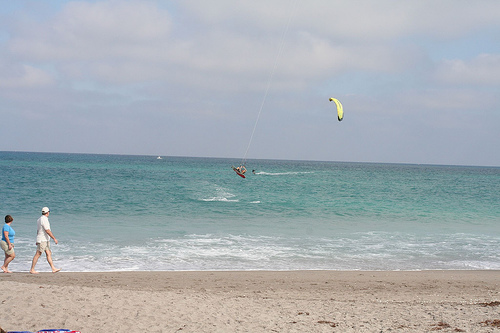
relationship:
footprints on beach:
[314, 317, 338, 326] [1, 247, 498, 329]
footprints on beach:
[481, 298, 498, 308] [1, 247, 498, 329]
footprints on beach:
[483, 317, 498, 326] [1, 247, 498, 329]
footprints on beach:
[433, 320, 453, 329] [1, 247, 498, 329]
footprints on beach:
[450, 327, 465, 331] [1, 247, 498, 329]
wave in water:
[189, 181, 261, 206] [1, 148, 497, 274]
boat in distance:
[155, 147, 170, 164] [2, 5, 498, 259]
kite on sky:
[324, 93, 348, 124] [4, 5, 494, 166]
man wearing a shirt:
[24, 204, 66, 279] [35, 214, 60, 246]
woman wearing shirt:
[0, 214, 17, 277] [0, 228, 18, 242]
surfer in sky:
[225, 156, 255, 185] [427, 36, 492, 56]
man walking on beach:
[24, 204, 66, 279] [2, 269, 484, 327]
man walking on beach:
[246, 160, 265, 178] [5, 236, 494, 290]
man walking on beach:
[24, 204, 66, 279] [51, 278, 134, 312]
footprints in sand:
[144, 279, 228, 328] [269, 260, 461, 322]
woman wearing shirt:
[0, 214, 17, 277] [3, 221, 15, 244]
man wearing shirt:
[24, 204, 66, 279] [32, 214, 56, 246]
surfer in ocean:
[225, 156, 255, 185] [44, 137, 480, 215]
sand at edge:
[4, 266, 499, 331] [8, 250, 499, 281]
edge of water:
[8, 250, 499, 281] [5, 150, 490, 245]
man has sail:
[246, 160, 265, 178] [320, 92, 348, 129]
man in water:
[246, 160, 265, 178] [241, 177, 387, 247]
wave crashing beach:
[70, 223, 494, 258] [1, 270, 499, 333]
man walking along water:
[24, 204, 66, 279] [164, 195, 267, 265]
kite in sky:
[324, 93, 348, 124] [45, 12, 308, 137]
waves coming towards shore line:
[63, 168, 393, 294] [136, 259, 478, 309]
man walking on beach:
[24, 204, 66, 279] [4, 266, 499, 331]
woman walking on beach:
[2, 216, 17, 276] [4, 266, 499, 331]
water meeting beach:
[5, 161, 499, 275] [2, 269, 484, 327]